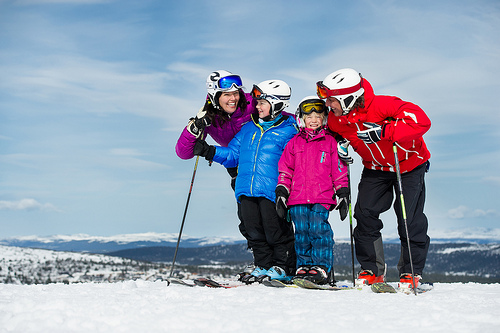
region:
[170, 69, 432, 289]
two women with kids snow skiing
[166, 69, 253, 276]
the woman in the purple ski jacket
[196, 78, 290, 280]
boy in the blue ski jacket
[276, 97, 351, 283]
little girl in the pink ski jacket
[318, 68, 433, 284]
the woman in the red ski jacket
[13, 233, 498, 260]
mountain range on the horizon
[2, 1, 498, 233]
mostly cloudy sky above the mountain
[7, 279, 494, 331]
snow covered ground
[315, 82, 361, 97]
red ski goggles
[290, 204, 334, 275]
blue ski pants on little girl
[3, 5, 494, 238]
blue sky covered with thin white clouds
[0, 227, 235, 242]
snow-capped mountain in distance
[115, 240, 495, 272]
dark mountain range behind people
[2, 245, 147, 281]
slope covered in snow and dotted with trees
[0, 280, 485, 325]
family on snow filled with footprints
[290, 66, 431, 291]
father leaning toward daughter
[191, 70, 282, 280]
mother leaning toward child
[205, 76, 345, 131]
adults and children smiling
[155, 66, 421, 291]
mother and father leaning on poles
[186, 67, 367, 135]
all members of family wearing helmets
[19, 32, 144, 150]
clouds in the sky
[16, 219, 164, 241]
mountains in the distance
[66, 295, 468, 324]
tracks in the snow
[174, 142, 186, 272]
a ski pole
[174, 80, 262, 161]
a woman in a purple jacket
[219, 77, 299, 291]
a kid in a blue jacket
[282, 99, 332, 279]
a girl in a pink jacket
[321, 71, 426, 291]
a person wearing a red jacket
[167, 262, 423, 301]
skis of the people standing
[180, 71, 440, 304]
people skiing on a mountain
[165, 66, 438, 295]
Family standing on top of a mountain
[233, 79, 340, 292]
Two young children wearing ski gear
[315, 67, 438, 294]
Male adult wearing red ski gear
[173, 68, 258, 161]
Female adult wearing purple ski gear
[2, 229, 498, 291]
Landscape of mountain tops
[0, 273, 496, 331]
Snow covered ground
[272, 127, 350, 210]
Bright pink winter jacket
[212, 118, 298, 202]
Bright blue winter jacket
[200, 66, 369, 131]
Ski helmets with goggles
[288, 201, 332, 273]
Blue ski pants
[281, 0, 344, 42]
clear patch of blue sky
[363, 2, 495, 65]
white clouds in sky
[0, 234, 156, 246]
mountain tops with snow in background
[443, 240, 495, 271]
closer mountains with snow tops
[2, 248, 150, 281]
grass with snow patches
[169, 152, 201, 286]
ski stick for support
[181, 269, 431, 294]
skis on feet for skiing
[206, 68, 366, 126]
helmets for protecting head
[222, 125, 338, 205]
winter coats for boys and girls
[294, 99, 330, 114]
goggle for eye protection